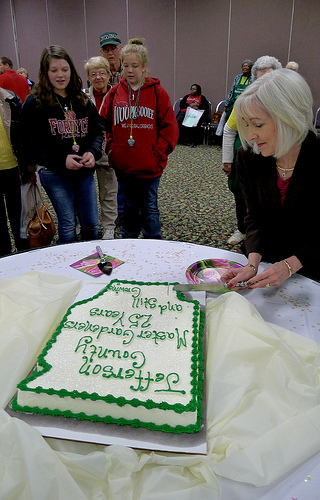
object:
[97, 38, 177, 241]
girl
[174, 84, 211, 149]
lady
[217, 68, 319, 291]
lady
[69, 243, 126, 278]
napkin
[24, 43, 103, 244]
person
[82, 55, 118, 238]
person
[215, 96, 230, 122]
chair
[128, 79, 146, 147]
necklace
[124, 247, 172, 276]
confetti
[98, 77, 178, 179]
shirt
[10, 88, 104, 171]
shirt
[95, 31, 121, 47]
green cap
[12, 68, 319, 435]
cutting cake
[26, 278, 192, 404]
frosting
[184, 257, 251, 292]
paper plate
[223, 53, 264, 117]
woman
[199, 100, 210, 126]
chair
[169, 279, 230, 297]
knife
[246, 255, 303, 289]
hands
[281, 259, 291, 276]
bracelet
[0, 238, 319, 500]
table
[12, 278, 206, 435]
cake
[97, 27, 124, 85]
man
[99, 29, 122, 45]
hat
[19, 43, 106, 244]
girl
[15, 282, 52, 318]
cloth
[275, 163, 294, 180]
necklace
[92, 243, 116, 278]
serving knife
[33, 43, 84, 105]
hair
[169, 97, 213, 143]
chair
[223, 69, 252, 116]
shirt